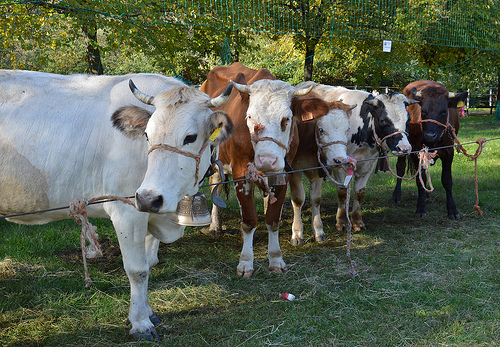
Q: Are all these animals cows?
A: Yes, all the animals are cows.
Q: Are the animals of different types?
A: No, all the animals are cows.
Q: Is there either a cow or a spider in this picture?
A: Yes, there is a cow.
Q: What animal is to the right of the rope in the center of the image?
A: The animal is a cow.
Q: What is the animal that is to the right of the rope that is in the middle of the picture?
A: The animal is a cow.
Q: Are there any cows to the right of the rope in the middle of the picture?
A: Yes, there is a cow to the right of the rope.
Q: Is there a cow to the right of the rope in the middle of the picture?
A: Yes, there is a cow to the right of the rope.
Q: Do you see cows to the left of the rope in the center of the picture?
A: No, the cow is to the right of the rope.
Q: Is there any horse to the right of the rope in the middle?
A: No, there is a cow to the right of the rope.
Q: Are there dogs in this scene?
A: No, there are no dogs.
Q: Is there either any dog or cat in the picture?
A: No, there are no dogs or cats.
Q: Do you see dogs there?
A: No, there are no dogs.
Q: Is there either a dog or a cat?
A: No, there are no dogs or cats.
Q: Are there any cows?
A: Yes, there is a cow.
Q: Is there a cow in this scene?
A: Yes, there is a cow.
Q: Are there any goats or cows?
A: Yes, there is a cow.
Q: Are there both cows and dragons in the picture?
A: No, there is a cow but no dragons.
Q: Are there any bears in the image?
A: No, there are no bears.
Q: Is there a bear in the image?
A: No, there are no bears.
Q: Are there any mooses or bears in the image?
A: No, there are no bears or mooses.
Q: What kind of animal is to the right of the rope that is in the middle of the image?
A: The animal is a cow.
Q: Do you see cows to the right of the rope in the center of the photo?
A: Yes, there is a cow to the right of the rope.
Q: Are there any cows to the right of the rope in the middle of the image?
A: Yes, there is a cow to the right of the rope.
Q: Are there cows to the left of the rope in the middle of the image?
A: No, the cow is to the right of the rope.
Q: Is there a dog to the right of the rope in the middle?
A: No, there is a cow to the right of the rope.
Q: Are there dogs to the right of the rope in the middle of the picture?
A: No, there is a cow to the right of the rope.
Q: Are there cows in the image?
A: Yes, there is a cow.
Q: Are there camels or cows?
A: Yes, there is a cow.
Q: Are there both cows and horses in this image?
A: No, there is a cow but no horses.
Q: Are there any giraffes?
A: No, there are no giraffes.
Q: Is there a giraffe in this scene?
A: No, there are no giraffes.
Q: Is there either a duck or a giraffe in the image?
A: No, there are no giraffes or ducks.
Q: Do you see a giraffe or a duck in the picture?
A: No, there are no giraffes or ducks.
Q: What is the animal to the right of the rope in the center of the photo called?
A: The animal is a cow.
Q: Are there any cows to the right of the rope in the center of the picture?
A: Yes, there is a cow to the right of the rope.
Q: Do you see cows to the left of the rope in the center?
A: No, the cow is to the right of the rope.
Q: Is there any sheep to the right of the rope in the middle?
A: No, there is a cow to the right of the rope.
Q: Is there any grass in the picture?
A: Yes, there is grass.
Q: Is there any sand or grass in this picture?
A: Yes, there is grass.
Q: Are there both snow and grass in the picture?
A: No, there is grass but no snow.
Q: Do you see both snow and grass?
A: No, there is grass but no snow.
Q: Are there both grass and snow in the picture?
A: No, there is grass but no snow.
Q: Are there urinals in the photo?
A: No, there are no urinals.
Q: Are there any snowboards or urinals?
A: No, there are no urinals or snowboards.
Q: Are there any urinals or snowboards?
A: No, there are no urinals or snowboards.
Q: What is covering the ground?
A: The grass is covering the ground.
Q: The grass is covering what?
A: The grass is covering the ground.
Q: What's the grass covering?
A: The grass is covering the ground.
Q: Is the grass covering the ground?
A: Yes, the grass is covering the ground.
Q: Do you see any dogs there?
A: No, there are no dogs.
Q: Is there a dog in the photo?
A: No, there are no dogs.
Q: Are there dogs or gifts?
A: No, there are no dogs or gifts.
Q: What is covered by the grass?
A: The ground is covered by the grass.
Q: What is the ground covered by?
A: The ground is covered by the grass.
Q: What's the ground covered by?
A: The ground is covered by the grass.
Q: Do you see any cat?
A: No, there are no cats.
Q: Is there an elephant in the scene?
A: No, there are no elephants.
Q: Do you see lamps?
A: No, there are no lamps.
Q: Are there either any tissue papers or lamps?
A: No, there are no lamps or tissue papers.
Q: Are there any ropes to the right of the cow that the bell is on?
A: Yes, there is a rope to the right of the cow.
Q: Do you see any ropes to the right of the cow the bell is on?
A: Yes, there is a rope to the right of the cow.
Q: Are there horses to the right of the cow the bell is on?
A: No, there is a rope to the right of the cow.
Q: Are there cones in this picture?
A: No, there are no cones.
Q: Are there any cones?
A: No, there are no cones.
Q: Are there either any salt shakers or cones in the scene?
A: No, there are no cones or salt shakers.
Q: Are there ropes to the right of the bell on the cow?
A: Yes, there is a rope to the right of the bell.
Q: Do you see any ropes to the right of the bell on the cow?
A: Yes, there is a rope to the right of the bell.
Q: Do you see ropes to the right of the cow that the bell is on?
A: Yes, there is a rope to the right of the cow.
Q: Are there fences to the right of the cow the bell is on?
A: No, there is a rope to the right of the cow.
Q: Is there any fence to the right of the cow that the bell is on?
A: No, there is a rope to the right of the cow.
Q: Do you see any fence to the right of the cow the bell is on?
A: No, there is a rope to the right of the cow.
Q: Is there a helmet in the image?
A: No, there are no helmets.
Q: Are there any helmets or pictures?
A: No, there are no helmets or pictures.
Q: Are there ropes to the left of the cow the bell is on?
A: Yes, there is a rope to the left of the cow.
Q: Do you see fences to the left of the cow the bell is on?
A: No, there is a rope to the left of the cow.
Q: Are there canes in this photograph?
A: No, there are no canes.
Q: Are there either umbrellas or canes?
A: No, there are no canes or umbrellas.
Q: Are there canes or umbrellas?
A: No, there are no canes or umbrellas.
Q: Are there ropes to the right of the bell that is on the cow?
A: Yes, there is a rope to the right of the bell.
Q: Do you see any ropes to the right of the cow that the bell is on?
A: Yes, there is a rope to the right of the cow.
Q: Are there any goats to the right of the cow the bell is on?
A: No, there is a rope to the right of the cow.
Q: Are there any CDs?
A: No, there are no cds.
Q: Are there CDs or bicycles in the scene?
A: No, there are no CDs or bicycles.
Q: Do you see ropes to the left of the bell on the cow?
A: Yes, there is a rope to the left of the bell.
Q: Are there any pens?
A: No, there are no pens.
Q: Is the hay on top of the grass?
A: Yes, the hay is on top of the grass.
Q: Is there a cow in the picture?
A: Yes, there is a cow.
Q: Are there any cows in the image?
A: Yes, there is a cow.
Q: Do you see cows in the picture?
A: Yes, there is a cow.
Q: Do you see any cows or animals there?
A: Yes, there is a cow.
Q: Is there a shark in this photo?
A: No, there are no sharks.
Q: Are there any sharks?
A: No, there are no sharks.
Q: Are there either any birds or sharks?
A: No, there are no sharks or birds.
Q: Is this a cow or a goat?
A: This is a cow.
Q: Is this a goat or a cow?
A: This is a cow.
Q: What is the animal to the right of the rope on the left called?
A: The animal is a cow.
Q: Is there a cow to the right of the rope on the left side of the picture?
A: Yes, there is a cow to the right of the rope.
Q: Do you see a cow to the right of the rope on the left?
A: Yes, there is a cow to the right of the rope.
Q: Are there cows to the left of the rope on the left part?
A: No, the cow is to the right of the rope.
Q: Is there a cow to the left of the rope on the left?
A: No, the cow is to the right of the rope.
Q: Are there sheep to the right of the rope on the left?
A: No, there is a cow to the right of the rope.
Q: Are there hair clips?
A: No, there are no hair clips.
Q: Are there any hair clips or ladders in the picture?
A: No, there are no hair clips or ladders.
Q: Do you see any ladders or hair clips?
A: No, there are no hair clips or ladders.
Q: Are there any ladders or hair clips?
A: No, there are no hair clips or ladders.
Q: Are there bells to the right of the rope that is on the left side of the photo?
A: Yes, there is a bell to the right of the rope.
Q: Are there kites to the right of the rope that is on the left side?
A: No, there is a bell to the right of the rope.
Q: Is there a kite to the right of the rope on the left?
A: No, there is a bell to the right of the rope.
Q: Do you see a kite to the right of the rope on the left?
A: No, there is a bell to the right of the rope.